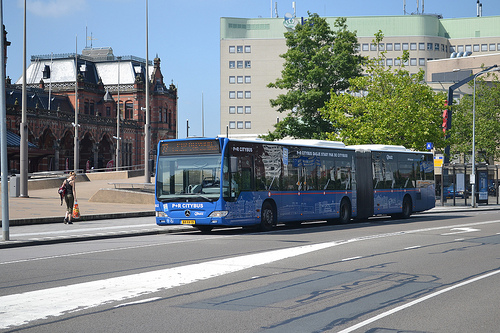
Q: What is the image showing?
A: It is showing a street.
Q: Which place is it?
A: It is a street.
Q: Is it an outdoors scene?
A: Yes, it is outdoors.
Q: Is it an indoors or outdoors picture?
A: It is outdoors.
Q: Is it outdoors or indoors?
A: It is outdoors.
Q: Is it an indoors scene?
A: No, it is outdoors.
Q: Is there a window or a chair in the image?
A: Yes, there is a window.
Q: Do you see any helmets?
A: No, there are no helmets.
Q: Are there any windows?
A: Yes, there is a window.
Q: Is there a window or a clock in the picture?
A: Yes, there is a window.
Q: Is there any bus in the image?
A: Yes, there is a bus.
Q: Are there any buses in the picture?
A: Yes, there is a bus.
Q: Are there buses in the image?
A: Yes, there is a bus.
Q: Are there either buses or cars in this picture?
A: Yes, there is a bus.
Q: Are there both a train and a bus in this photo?
A: No, there is a bus but no trains.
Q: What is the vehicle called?
A: The vehicle is a bus.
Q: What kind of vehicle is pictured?
A: The vehicle is a bus.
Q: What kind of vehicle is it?
A: The vehicle is a bus.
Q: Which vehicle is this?
A: This is a bus.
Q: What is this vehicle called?
A: This is a bus.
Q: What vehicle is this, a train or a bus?
A: This is a bus.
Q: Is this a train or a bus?
A: This is a bus.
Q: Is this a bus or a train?
A: This is a bus.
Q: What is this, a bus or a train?
A: This is a bus.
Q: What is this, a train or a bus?
A: This is a bus.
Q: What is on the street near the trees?
A: The bus is on the street.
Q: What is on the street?
A: The bus is on the street.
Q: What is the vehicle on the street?
A: The vehicle is a bus.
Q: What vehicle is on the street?
A: The vehicle is a bus.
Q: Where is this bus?
A: The bus is on the street.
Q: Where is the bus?
A: The bus is on the street.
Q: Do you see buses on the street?
A: Yes, there is a bus on the street.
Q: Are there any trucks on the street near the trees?
A: No, there is a bus on the street.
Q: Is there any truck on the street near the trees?
A: No, there is a bus on the street.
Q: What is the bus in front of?
A: The bus is in front of the building.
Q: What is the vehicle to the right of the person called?
A: The vehicle is a bus.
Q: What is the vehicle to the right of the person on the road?
A: The vehicle is a bus.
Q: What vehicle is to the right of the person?
A: The vehicle is a bus.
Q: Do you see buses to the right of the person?
A: Yes, there is a bus to the right of the person.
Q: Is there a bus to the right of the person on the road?
A: Yes, there is a bus to the right of the person.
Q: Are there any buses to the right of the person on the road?
A: Yes, there is a bus to the right of the person.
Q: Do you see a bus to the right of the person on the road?
A: Yes, there is a bus to the right of the person.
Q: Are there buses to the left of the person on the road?
A: No, the bus is to the right of the person.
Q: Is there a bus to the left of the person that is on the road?
A: No, the bus is to the right of the person.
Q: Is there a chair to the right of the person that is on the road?
A: No, there is a bus to the right of the person.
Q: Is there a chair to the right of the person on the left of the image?
A: No, there is a bus to the right of the person.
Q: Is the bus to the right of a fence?
A: No, the bus is to the right of a person.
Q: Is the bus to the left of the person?
A: No, the bus is to the right of the person.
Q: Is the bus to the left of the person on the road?
A: No, the bus is to the right of the person.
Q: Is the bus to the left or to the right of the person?
A: The bus is to the right of the person.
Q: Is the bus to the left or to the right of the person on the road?
A: The bus is to the right of the person.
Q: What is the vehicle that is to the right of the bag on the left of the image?
A: The vehicle is a bus.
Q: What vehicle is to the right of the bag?
A: The vehicle is a bus.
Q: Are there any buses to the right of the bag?
A: Yes, there is a bus to the right of the bag.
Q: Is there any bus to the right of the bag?
A: Yes, there is a bus to the right of the bag.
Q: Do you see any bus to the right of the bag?
A: Yes, there is a bus to the right of the bag.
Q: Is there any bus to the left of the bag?
A: No, the bus is to the right of the bag.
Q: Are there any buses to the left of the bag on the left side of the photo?
A: No, the bus is to the right of the bag.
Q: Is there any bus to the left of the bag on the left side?
A: No, the bus is to the right of the bag.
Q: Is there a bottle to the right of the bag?
A: No, there is a bus to the right of the bag.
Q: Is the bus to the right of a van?
A: No, the bus is to the right of a bag.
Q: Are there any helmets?
A: No, there are no helmets.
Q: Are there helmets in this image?
A: No, there are no helmets.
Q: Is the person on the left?
A: Yes, the person is on the left of the image.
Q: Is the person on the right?
A: No, the person is on the left of the image.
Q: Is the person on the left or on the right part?
A: The person is on the left of the image.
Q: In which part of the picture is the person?
A: The person is on the left of the image.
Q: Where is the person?
A: The person is on the road.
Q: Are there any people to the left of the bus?
A: Yes, there is a person to the left of the bus.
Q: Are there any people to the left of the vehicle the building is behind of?
A: Yes, there is a person to the left of the bus.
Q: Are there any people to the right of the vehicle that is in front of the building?
A: No, the person is to the left of the bus.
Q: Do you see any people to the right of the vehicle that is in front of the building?
A: No, the person is to the left of the bus.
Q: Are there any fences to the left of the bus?
A: No, there is a person to the left of the bus.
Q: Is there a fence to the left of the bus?
A: No, there is a person to the left of the bus.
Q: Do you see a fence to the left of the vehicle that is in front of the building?
A: No, there is a person to the left of the bus.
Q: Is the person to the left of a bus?
A: Yes, the person is to the left of a bus.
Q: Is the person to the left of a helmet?
A: No, the person is to the left of a bus.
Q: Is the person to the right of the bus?
A: No, the person is to the left of the bus.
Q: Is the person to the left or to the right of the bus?
A: The person is to the left of the bus.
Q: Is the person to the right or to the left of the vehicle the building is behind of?
A: The person is to the left of the bus.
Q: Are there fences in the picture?
A: No, there are no fences.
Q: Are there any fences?
A: No, there are no fences.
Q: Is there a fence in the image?
A: No, there are no fences.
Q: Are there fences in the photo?
A: No, there are no fences.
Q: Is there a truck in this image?
A: No, there are no trucks.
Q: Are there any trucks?
A: No, there are no trucks.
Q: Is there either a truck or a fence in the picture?
A: No, there are no trucks or fences.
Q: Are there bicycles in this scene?
A: No, there are no bicycles.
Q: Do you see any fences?
A: No, there are no fences.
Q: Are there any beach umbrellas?
A: No, there are no beach umbrellas.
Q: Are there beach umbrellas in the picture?
A: No, there are no beach umbrellas.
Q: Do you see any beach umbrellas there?
A: No, there are no beach umbrellas.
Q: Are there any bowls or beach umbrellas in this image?
A: No, there are no beach umbrellas or bowls.